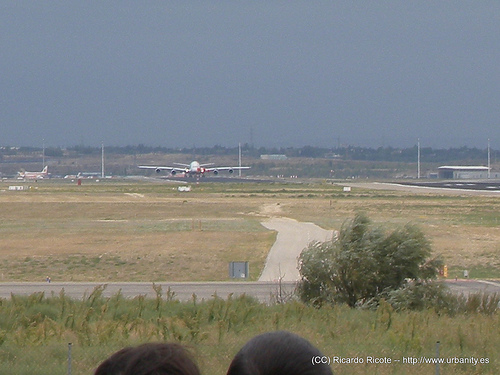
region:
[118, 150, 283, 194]
the airplane on the runway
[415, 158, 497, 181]
the hangar for planes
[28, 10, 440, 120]
the sky is gray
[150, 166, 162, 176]
the engine of the plane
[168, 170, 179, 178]
the engine of the plane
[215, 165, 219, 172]
the engine of the plane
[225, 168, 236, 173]
the engine of the plane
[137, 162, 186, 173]
the wing of the plane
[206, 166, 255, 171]
the wing of the plane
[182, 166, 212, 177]
the lights on the plane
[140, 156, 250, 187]
the plane on the runway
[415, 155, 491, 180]
the hangar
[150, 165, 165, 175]
engine on the plane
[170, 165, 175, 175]
the engine on the plane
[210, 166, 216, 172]
engine on the plane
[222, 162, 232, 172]
engine on the plane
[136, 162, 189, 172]
wing of the plane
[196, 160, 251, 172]
wing of the plane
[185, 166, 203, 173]
lights on the plane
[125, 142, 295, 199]
a plane in the distance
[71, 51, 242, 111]
the sky is overcast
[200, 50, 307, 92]
the sky is overcast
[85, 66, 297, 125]
the sky is overcast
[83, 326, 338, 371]
Two persons watching the airport from a distance.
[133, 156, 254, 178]
Airplane moving slowly on the runway.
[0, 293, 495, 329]
Side of the runway is bushy.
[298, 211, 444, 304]
Tree blown by the wind.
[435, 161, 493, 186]
Airplane hangar at the airport.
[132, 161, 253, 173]
Aircraft with very large wings.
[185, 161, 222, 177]
The tail of the airplane is red.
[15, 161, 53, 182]
Another smaller aircraft on the ground.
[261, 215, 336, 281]
Small road next to the runways.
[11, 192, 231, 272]
Very dry grass.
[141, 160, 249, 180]
An airplane on the runway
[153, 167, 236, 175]
Engines on the airplane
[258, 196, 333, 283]
A path between the grass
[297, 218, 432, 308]
A tree near the runway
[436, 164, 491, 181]
A hangar at the airport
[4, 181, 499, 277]
Grass at the airport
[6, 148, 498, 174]
A hill behind the airplane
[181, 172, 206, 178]
Wheels on the airplane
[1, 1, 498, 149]
The sky above the airplane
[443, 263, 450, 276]
A yellow pole near the grass